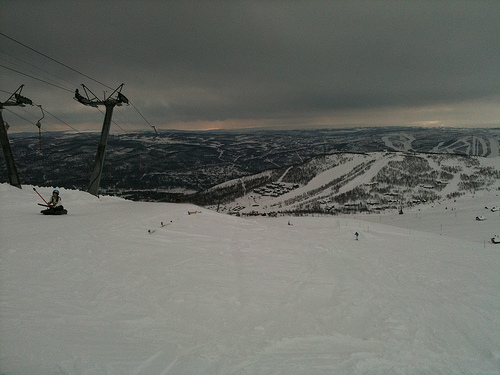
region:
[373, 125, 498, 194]
tracks in the snow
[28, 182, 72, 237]
person in the snow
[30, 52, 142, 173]
power lines going down the mountain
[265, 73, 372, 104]
gray clouds in the sky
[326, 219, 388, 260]
person skiing down the hill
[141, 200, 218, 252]
trail markers on a ski trail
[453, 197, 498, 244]
cars parked in the parking lot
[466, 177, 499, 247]
cars covered in snow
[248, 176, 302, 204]
parking lot with snow covered cars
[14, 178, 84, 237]
person taking a fall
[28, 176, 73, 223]
Woman sitting on a sled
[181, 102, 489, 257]
Mountain with ski paths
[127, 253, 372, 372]
The snow has tracks in it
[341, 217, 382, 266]
Person skiing down the hill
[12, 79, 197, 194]
Lift for ski chairs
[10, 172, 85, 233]
Woman wearing coat and snow pants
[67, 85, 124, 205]
Pole holding up ski lift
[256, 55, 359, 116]
Storm clouds in the sky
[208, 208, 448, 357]
Snowy mountain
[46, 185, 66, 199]
Woman wearing a helmet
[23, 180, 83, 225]
One skier up close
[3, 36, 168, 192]
ski lift for skiers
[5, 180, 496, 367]
snow covered ski slope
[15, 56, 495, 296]
many skiers in the background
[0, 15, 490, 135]
blue gray skyline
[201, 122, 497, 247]
snow covered roads or paths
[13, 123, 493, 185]
snow covered hills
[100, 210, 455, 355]
ski tracks in the snow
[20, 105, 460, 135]
pink skyline in background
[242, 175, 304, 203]
houses or parking lot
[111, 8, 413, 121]
dark gray storm clouds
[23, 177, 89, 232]
a skier sitting on the ground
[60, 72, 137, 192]
posts of the chairlift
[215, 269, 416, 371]
tracks in the white snow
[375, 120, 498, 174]
ski tracks in the snow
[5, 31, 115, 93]
chairlift cables in the air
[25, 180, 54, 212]
a person holding ski poles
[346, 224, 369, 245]
skier going down the mountain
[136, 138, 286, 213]
trees covered in snow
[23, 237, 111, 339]
fresh white snow on the ground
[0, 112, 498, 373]
Mountains are in the distance.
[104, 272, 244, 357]
Snow is on the ground.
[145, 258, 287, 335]
The snow is white.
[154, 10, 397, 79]
Clouds are in the sky.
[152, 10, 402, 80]
The sky is gray.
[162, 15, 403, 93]
The clouds are gray.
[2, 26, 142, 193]
A ski lift.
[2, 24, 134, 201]
The ski lift is made of metal.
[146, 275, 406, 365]
The snow is thick.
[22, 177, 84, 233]
A person skiing.